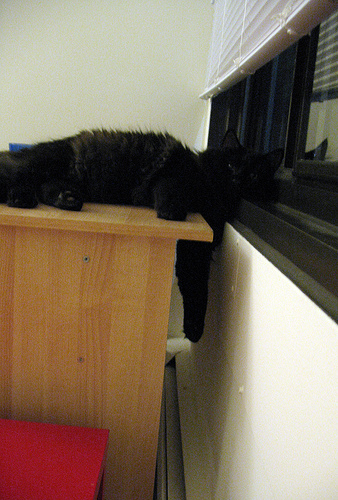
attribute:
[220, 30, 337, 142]
window — glass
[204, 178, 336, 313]
window ledge — black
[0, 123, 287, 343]
cat — black, awake, big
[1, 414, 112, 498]
chair — red, wooden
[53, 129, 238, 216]
fur — black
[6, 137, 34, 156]
object — blue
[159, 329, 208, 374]
vent — white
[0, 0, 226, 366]
wall — clean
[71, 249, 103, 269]
screw — round, metal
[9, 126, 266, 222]
cat — black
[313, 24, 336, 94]
blinds — white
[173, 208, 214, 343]
paw — dangling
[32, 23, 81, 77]
wall — white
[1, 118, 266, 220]
cat — fluffy, black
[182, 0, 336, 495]
wall — white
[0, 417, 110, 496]
table — red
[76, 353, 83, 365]
screw — metal, round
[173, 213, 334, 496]
wall — white, square